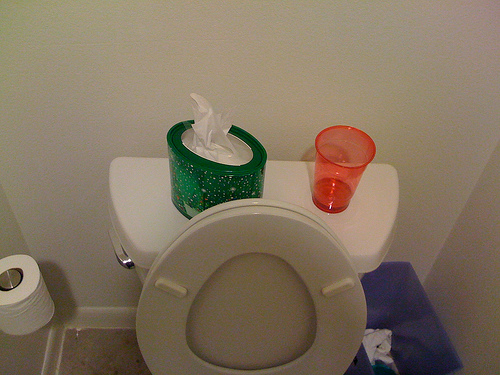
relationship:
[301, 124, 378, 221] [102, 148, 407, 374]
cup on top of toilet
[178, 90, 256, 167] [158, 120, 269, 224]
tissue paper in dispenser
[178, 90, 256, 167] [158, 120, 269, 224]
tissue paper inside of dispenser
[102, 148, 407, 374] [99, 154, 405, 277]
toilet has lid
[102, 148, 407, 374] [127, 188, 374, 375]
toilet has seat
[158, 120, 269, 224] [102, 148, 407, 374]
dispenser on top of toilet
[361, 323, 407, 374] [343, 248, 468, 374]
trash inside of waste basket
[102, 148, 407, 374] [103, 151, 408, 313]
toilet has tank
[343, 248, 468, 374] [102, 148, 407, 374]
waste basket next to toilet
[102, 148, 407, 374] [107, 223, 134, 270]
toilet has lever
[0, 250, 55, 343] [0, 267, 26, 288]
toilet paper on top of roll holder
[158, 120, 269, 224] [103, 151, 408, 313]
dispenser on top of tank